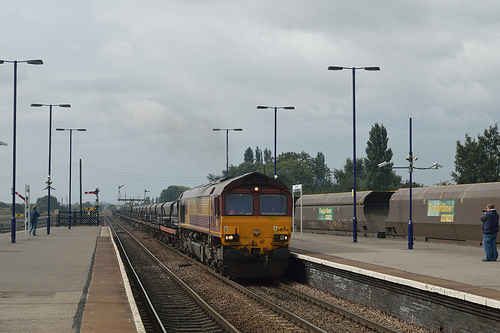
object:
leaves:
[450, 142, 494, 170]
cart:
[176, 171, 296, 279]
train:
[111, 170, 294, 281]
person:
[28, 205, 41, 237]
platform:
[1, 224, 146, 332]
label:
[196, 197, 203, 214]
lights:
[224, 234, 240, 242]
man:
[481, 202, 499, 261]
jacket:
[479, 209, 500, 234]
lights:
[327, 63, 383, 73]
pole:
[351, 67, 360, 243]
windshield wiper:
[279, 189, 283, 213]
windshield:
[224, 193, 290, 216]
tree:
[450, 122, 499, 182]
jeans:
[483, 230, 500, 260]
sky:
[1, 0, 500, 204]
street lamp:
[30, 100, 70, 235]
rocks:
[118, 216, 304, 332]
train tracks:
[102, 205, 500, 332]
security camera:
[378, 161, 388, 167]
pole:
[407, 116, 416, 250]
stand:
[83, 206, 99, 226]